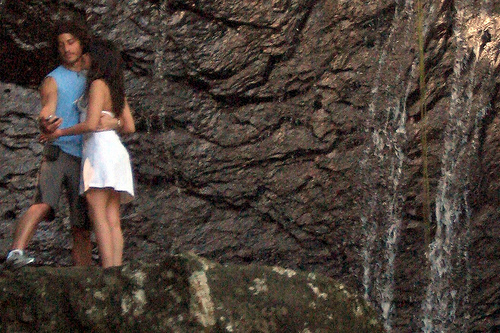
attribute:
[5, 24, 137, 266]
couple — hugging, posing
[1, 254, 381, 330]
rock — gray, white, rough textured, black, large, slick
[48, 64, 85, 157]
shirt — blue, sleeveless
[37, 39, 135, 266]
lady — happy, dressed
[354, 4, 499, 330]
water — falling, clear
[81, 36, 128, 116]
hair — long, dark, black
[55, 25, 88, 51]
hair — dark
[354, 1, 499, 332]
waterfall — small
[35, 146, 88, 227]
shorts — black, gray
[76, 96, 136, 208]
dress — short, white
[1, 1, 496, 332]
rock wall — dark, black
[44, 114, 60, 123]
phone — black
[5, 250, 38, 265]
sneakers — gray